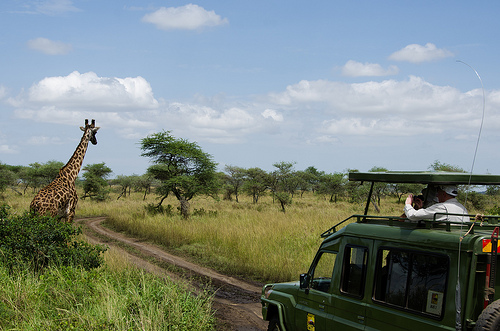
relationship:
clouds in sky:
[394, 40, 456, 70] [2, 0, 483, 172]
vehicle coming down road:
[259, 167, 499, 331] [108, 233, 186, 271]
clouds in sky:
[259, 77, 492, 123] [0, 2, 499, 188]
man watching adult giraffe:
[403, 181, 471, 224] [30, 119, 101, 225]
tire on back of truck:
[478, 283, 496, 305] [215, 197, 475, 298]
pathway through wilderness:
[79, 211, 266, 314] [4, 163, 340, 313]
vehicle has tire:
[259, 167, 498, 327] [263, 305, 287, 329]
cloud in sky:
[381, 39, 458, 68] [0, 2, 499, 188]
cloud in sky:
[327, 55, 404, 84] [0, 2, 499, 188]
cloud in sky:
[144, 3, 234, 30] [0, 2, 499, 188]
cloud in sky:
[15, 32, 76, 62] [0, 2, 499, 188]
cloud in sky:
[31, 68, 156, 112] [0, 2, 499, 188]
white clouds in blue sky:
[340, 35, 450, 112] [226, 14, 353, 75]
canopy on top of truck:
[351, 170, 484, 188] [263, 152, 499, 318]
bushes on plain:
[3, 212, 100, 278] [90, 193, 311, 276]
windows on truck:
[376, 240, 457, 320] [259, 227, 497, 329]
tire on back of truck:
[478, 300, 500, 331] [290, 182, 495, 324]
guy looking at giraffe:
[395, 181, 472, 228] [27, 115, 103, 232]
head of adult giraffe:
[78, 117, 101, 149] [30, 117, 100, 229]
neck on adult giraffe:
[57, 134, 90, 181] [30, 119, 101, 225]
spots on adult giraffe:
[31, 139, 88, 216] [30, 119, 101, 225]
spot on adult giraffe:
[51, 190, 60, 202] [30, 119, 101, 225]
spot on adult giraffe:
[64, 170, 78, 179] [30, 119, 101, 225]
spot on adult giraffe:
[69, 150, 79, 160] [30, 119, 101, 225]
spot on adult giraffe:
[32, 192, 46, 202] [30, 119, 101, 225]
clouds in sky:
[73, 76, 162, 111] [94, 14, 176, 70]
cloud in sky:
[31, 68, 156, 112] [238, 46, 318, 81]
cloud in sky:
[144, 3, 234, 30] [238, 46, 318, 81]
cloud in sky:
[388, 44, 451, 64] [238, 46, 318, 81]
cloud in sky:
[265, 74, 483, 134] [238, 46, 318, 81]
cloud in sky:
[31, 68, 156, 112] [2, 0, 483, 172]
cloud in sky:
[144, 3, 234, 30] [2, 0, 483, 172]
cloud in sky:
[388, 44, 451, 64] [2, 0, 483, 172]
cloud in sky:
[265, 74, 483, 134] [2, 0, 483, 172]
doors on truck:
[310, 295, 362, 328] [267, 215, 498, 325]